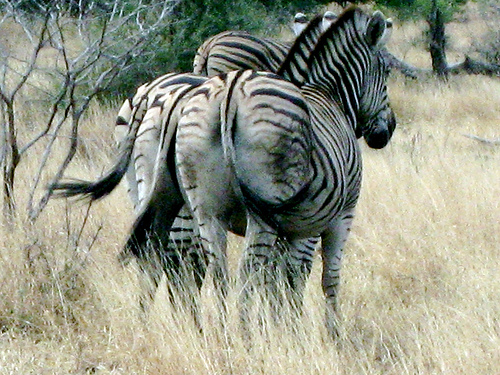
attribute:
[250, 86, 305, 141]
stripe — black, white, stripes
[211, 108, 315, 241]
tail — black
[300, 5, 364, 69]
hair — black